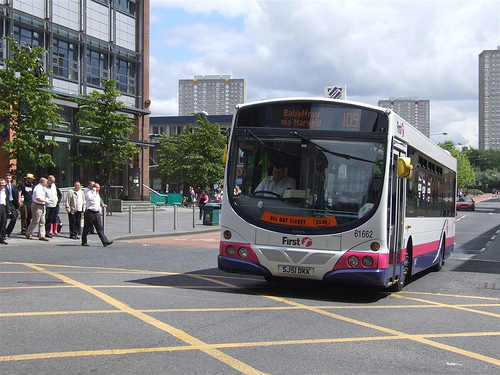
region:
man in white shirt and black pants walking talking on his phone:
[78, 177, 115, 249]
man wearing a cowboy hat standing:
[15, 168, 37, 239]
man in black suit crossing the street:
[3, 170, 20, 234]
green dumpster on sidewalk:
[199, 199, 220, 229]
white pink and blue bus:
[214, 95, 459, 298]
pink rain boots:
[45, 218, 60, 239]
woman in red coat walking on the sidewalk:
[194, 186, 211, 221]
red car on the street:
[453, 193, 476, 215]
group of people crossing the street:
[0, 167, 117, 252]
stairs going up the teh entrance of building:
[104, 197, 166, 212]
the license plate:
[279, 265, 315, 277]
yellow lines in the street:
[184, 325, 228, 361]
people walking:
[3, 171, 118, 252]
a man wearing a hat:
[20, 169, 37, 181]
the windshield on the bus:
[240, 136, 369, 205]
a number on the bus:
[338, 109, 360, 133]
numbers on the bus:
[351, 230, 373, 241]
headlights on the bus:
[345, 254, 372, 267]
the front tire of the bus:
[402, 243, 418, 280]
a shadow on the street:
[142, 275, 189, 287]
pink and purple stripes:
[287, 240, 494, 281]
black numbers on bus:
[338, 216, 380, 253]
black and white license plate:
[272, 260, 319, 287]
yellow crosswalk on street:
[25, 234, 467, 374]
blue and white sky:
[170, 6, 340, 88]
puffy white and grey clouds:
[231, 14, 481, 110]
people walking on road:
[1, 186, 121, 251]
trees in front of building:
[2, 54, 211, 209]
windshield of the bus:
[235, 100, 380, 226]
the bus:
[222, 104, 389, 269]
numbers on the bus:
[350, 230, 376, 237]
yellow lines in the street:
[171, 326, 208, 346]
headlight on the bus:
[365, 238, 382, 253]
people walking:
[20, 173, 120, 250]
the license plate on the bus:
[277, 263, 313, 275]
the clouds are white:
[325, 28, 435, 69]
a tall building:
[178, 75, 240, 110]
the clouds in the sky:
[280, 18, 449, 81]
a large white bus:
[183, 80, 490, 318]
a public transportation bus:
[218, 99, 455, 298]